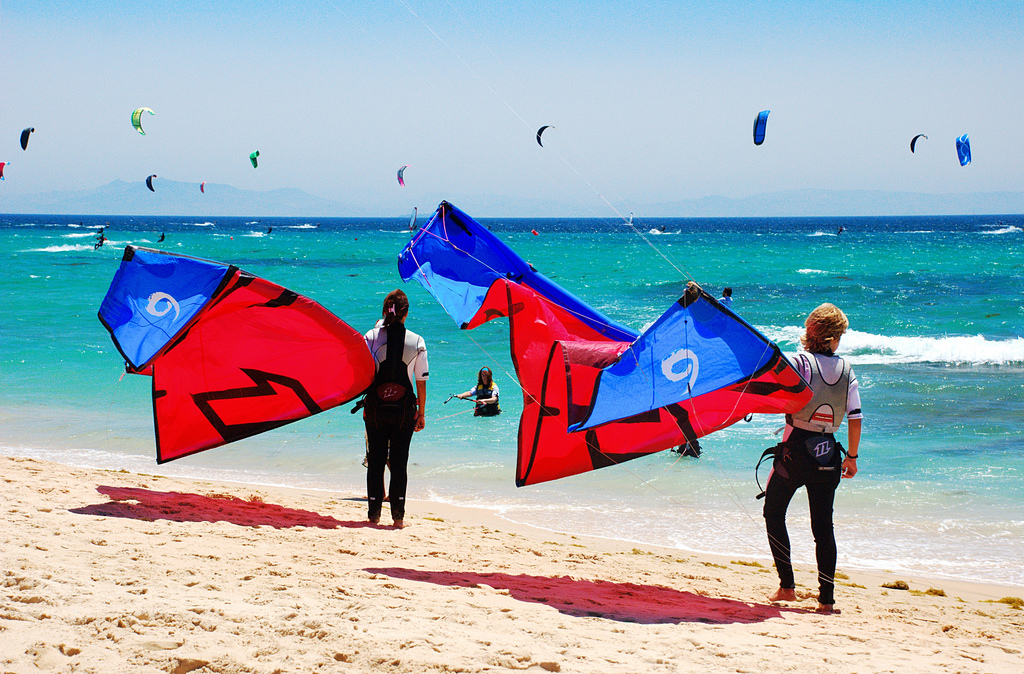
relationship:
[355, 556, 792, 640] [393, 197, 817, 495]
shadow of kite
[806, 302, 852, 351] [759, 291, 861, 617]
hair belonging to man